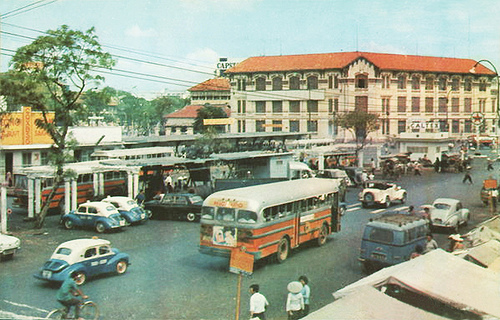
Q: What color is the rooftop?
A: Red.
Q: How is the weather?
A: Clear.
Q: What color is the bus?
A: Red and white.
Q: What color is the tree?
A: Green.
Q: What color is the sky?
A: Blue.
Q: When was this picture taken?
A: Daytime.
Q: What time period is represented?
A: 1950's.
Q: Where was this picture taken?
A: Italy.